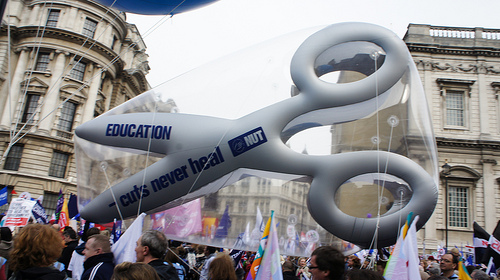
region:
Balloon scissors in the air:
[74, 23, 429, 242]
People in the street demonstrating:
[1, 220, 498, 278]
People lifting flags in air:
[49, 205, 498, 279]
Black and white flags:
[472, 222, 499, 264]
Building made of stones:
[405, 24, 497, 251]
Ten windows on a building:
[2, 7, 97, 211]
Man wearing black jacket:
[77, 235, 113, 278]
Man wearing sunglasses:
[306, 248, 348, 276]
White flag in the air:
[259, 211, 282, 278]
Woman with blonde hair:
[11, 220, 64, 267]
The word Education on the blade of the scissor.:
[102, 117, 182, 149]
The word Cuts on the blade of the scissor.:
[112, 183, 153, 203]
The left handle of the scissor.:
[261, 29, 409, 105]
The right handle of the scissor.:
[316, 158, 432, 242]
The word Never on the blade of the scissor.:
[140, 162, 194, 192]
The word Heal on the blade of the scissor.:
[182, 146, 231, 171]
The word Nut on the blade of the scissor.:
[235, 125, 266, 143]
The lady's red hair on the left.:
[12, 225, 61, 267]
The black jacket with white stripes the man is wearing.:
[76, 253, 106, 278]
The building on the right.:
[402, 14, 498, 246]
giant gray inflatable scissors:
[72, 20, 439, 247]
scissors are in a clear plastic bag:
[76, 14, 443, 259]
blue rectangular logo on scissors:
[226, 125, 267, 155]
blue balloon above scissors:
[98, 0, 217, 15]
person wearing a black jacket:
[76, 234, 113, 279]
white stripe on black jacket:
[88, 259, 107, 279]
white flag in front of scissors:
[104, 210, 147, 265]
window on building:
[59, 98, 79, 131]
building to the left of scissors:
[0, 0, 174, 215]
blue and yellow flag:
[456, 253, 474, 279]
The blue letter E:
[101, 117, 121, 138]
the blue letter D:
[106, 120, 123, 137]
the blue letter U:
[117, 120, 131, 137]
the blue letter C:
[126, 120, 141, 142]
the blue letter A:
[131, 123, 148, 141]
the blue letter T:
[140, 120, 156, 140]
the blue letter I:
[149, 120, 159, 140]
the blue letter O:
[151, 123, 166, 143]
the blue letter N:
[156, 119, 178, 149]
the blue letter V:
[158, 170, 181, 186]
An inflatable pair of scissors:
[148, 123, 215, 173]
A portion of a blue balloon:
[125, 3, 183, 10]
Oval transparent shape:
[309, 40, 390, 84]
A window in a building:
[442, 89, 466, 125]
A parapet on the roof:
[433, 28, 476, 38]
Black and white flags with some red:
[478, 232, 498, 255]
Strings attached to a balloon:
[12, 113, 24, 138]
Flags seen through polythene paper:
[196, 211, 233, 238]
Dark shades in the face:
[308, 264, 315, 270]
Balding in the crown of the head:
[153, 232, 165, 239]